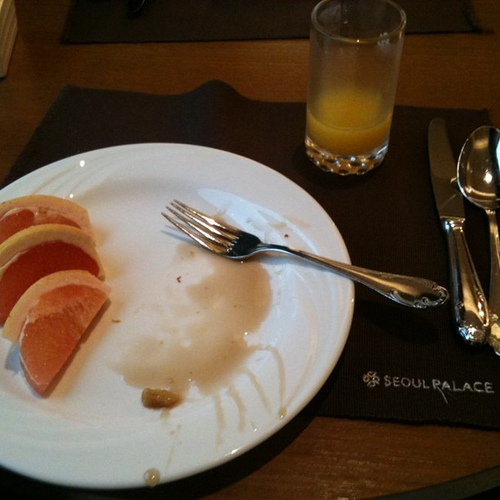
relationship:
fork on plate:
[164, 200, 449, 310] [0, 142, 356, 491]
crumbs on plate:
[107, 230, 289, 325] [0, 142, 356, 491]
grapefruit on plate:
[0, 193, 111, 394] [0, 142, 356, 491]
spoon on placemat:
[457, 122, 499, 357] [1, 78, 500, 429]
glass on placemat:
[302, 0, 406, 177] [1, 78, 500, 429]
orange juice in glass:
[306, 87, 394, 156] [302, 0, 406, 177]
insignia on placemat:
[363, 370, 495, 395] [1, 78, 500, 429]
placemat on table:
[1, 78, 500, 429] [0, 0, 499, 499]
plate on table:
[0, 142, 356, 491] [0, 0, 499, 499]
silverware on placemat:
[427, 116, 500, 358] [1, 78, 500, 429]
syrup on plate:
[108, 216, 287, 452] [0, 142, 356, 491]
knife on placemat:
[428, 116, 488, 347] [1, 78, 500, 429]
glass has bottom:
[302, 0, 406, 177] [303, 132, 390, 176]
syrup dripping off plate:
[108, 216, 287, 452] [0, 142, 356, 491]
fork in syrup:
[164, 200, 449, 310] [108, 216, 287, 452]